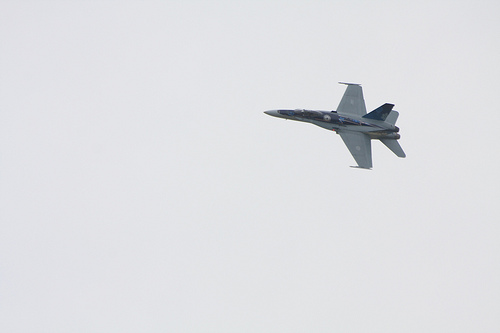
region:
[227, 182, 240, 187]
edge of a cloud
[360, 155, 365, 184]
part of a plane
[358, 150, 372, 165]
part of a wing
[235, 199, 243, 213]
edge of a cloud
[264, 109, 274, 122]
tip of a plane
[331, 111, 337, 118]
part of a window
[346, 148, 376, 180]
edge of a wimg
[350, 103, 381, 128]
part of a planr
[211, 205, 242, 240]
[art of a vclud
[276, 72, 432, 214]
plane is in the air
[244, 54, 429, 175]
the plane is bent at one side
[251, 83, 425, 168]
the plane is moving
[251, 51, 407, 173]
plane is moving in a horizontal motion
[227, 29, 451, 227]
the sky is clear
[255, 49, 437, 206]
the shade is black and white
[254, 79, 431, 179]
the plane is white in color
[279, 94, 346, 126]
the back ia black in color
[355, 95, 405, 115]
the tail is black in color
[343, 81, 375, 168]
the wings have logos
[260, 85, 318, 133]
front of a plane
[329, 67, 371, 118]
wing of a plane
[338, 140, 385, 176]
wing of a plane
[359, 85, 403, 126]
wing of a plane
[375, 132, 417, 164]
wing of a plane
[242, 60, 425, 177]
plane in the sky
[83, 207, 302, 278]
clear blue sky with no clouds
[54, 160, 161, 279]
a clear blue sky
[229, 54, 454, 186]
a jet in the sky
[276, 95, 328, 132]
cockpit of a plane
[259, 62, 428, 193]
silver aircraft in sky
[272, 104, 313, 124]
cockpit on silver aircraft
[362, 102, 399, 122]
blue tail fin on silver aircraft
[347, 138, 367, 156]
small white design on aircraft wing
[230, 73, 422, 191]
fighter jet flying in sky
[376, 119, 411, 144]
jet engine on back of aircraft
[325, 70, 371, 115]
wing on side of aircraft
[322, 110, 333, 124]
design on cockpit of aircraft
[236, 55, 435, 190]
silver aircraft in cloudy sky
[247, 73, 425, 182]
silver jet aircraft flying in cloudy sky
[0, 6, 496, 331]
gray clear sky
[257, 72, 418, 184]
small gray fighter plane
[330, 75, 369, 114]
gray plane wing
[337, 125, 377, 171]
gray plane wing